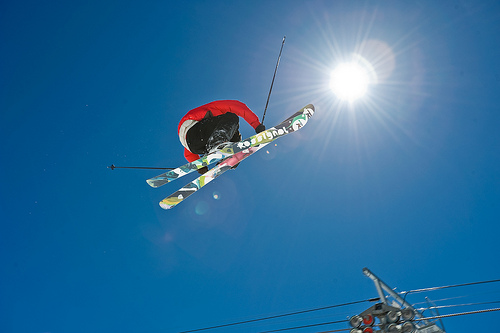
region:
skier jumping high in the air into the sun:
[105, 36, 317, 211]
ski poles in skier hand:
[257, 32, 286, 125]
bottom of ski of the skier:
[113, 105, 328, 208]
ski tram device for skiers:
[302, 267, 462, 330]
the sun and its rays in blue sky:
[250, 6, 454, 162]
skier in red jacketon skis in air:
[150, 101, 263, 175]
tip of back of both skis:
[140, 176, 190, 212]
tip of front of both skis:
[284, 101, 322, 136]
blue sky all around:
[5, 2, 290, 330]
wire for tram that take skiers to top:
[168, 292, 377, 332]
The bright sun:
[309, 42, 391, 127]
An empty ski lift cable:
[197, 260, 495, 331]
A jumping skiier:
[170, 95, 264, 163]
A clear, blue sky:
[4, 7, 164, 159]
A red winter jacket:
[179, 96, 262, 126]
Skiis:
[141, 107, 316, 210]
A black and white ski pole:
[259, 32, 288, 124]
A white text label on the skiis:
[231, 122, 293, 154]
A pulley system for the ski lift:
[343, 302, 423, 332]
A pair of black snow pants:
[183, 109, 241, 156]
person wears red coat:
[124, 45, 356, 231]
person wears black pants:
[155, 126, 255, 152]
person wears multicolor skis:
[160, 68, 341, 202]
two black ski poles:
[104, 150, 249, 204]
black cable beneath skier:
[263, 282, 490, 327]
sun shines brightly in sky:
[319, 45, 367, 107]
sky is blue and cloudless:
[34, 106, 119, 235]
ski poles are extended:
[89, 25, 346, 197]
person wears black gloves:
[247, 120, 260, 144]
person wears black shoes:
[202, 127, 257, 164]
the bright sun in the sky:
[319, 39, 381, 111]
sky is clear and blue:
[15, 36, 175, 144]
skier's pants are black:
[187, 114, 236, 146]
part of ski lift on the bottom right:
[344, 266, 470, 331]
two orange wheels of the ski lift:
[362, 312, 375, 331]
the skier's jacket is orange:
[180, 98, 257, 125]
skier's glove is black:
[255, 123, 267, 133]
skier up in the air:
[144, 97, 317, 210]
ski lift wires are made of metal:
[415, 282, 498, 319]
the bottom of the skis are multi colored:
[145, 102, 317, 212]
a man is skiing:
[80, 29, 400, 254]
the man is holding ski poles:
[100, 33, 305, 174]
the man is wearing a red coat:
[150, 85, 278, 172]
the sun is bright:
[245, 32, 422, 157]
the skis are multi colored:
[154, 98, 321, 224]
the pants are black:
[159, 104, 268, 202]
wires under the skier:
[230, 247, 479, 330]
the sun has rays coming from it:
[242, 28, 437, 170]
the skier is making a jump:
[72, 42, 354, 218]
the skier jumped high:
[49, 22, 366, 234]